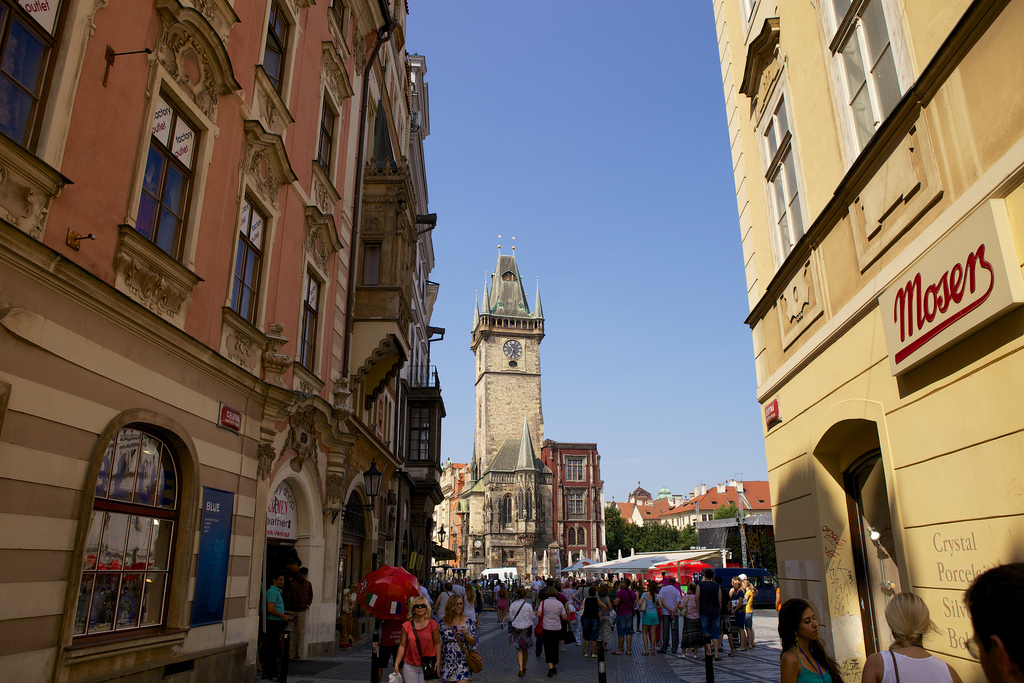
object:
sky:
[410, 0, 760, 436]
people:
[659, 576, 683, 655]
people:
[611, 578, 636, 669]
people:
[635, 581, 663, 649]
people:
[677, 581, 702, 656]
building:
[469, 234, 548, 556]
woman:
[778, 597, 847, 682]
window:
[55, 406, 202, 666]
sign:
[877, 198, 1024, 378]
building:
[605, 478, 774, 541]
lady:
[391, 596, 443, 682]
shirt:
[877, 650, 949, 682]